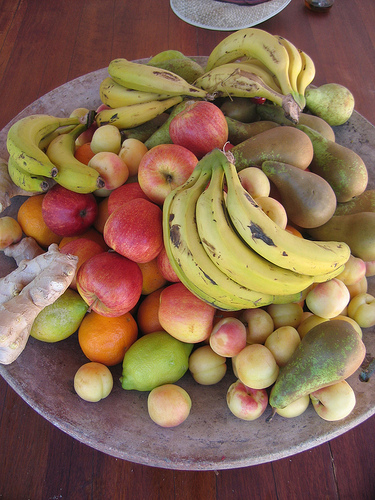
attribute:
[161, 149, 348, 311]
bananas — yellow, ripe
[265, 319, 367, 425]
pear — green, brown, yellow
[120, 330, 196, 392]
lemon — green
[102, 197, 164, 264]
apple — red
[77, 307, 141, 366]
orange — round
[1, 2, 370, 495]
table — wooden, brown, wood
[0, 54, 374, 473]
tray — grey, brown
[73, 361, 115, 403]
peach — yellow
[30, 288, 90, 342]
lime — green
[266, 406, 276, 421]
stem — brown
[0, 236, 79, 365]
ginger — tan, deformed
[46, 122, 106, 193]
banana — yellow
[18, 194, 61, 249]
fruit — orange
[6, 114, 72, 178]
banana — green